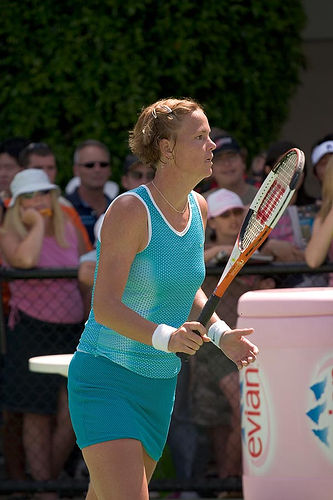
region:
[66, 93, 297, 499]
a lady playing tennis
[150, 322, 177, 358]
a white sweat band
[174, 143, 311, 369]
a orange and black tennis racket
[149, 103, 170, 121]
pins in ladys hair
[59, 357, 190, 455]
a short blue skirt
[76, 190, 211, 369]
a blue tank top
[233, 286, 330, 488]
a large pink cooler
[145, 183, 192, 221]
a gold necklace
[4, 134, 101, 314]
a crowd watching a game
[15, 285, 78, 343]
chain link fence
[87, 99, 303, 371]
a woman in blue playing tennis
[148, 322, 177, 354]
white wrist band on a wrist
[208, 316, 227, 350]
white wrist band on a wrist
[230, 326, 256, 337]
the thumb of a hand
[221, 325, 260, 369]
the hand of a woman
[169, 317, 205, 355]
the hand of a woman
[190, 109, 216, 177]
the face of a woman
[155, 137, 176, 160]
the ear of a woman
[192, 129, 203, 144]
the eye of a woman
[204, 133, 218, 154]
the nose of a woman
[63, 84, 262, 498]
female tennis player Lindsay Davenport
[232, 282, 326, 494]
pink, blue and white evian water cooler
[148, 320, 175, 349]
white sport wrist band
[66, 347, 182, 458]
blue tennis skirt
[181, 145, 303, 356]
Wilson wooden tennis racket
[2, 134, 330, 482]
spectators watching Lindsay Davenport tennis match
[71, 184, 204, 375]
blue and white tennis tank top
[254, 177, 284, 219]
Wilson sporting goods company logo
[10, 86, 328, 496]
Lindsay Davenport preparing to receive the serve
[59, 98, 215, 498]
female tennis player Lindsay Davenport wearing blue and white tennis clothes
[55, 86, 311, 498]
a woman playing tennis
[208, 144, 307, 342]
a Wilson tennis racket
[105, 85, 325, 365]
a woman holding a tennis racket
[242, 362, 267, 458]
the Evian logo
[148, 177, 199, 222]
a gold necklace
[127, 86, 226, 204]
a woman with blonde hair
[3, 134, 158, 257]
the spectators at a tennis match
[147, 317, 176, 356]
a white tennis wristband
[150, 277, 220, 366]
a hand gripping a tennis racket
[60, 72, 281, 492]
A woman playing tennis.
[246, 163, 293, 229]
The letter W on strings of tennis racket.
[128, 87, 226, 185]
A woman with very short hair.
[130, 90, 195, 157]
Barrettes in a woman's hair.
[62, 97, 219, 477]
Woman is wearing a turquoise outfit.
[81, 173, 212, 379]
A tank top with white trim around neck and arms.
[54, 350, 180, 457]
A turquoise tennis skirt.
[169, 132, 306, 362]
Tennis racquet in woman's right hand.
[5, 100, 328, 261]
Spectators watching a tennis game.